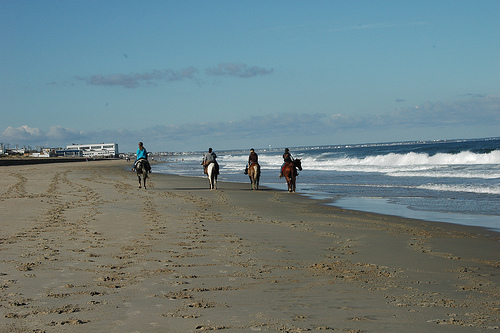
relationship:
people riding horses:
[133, 138, 298, 164] [130, 139, 309, 196]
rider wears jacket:
[132, 138, 154, 175] [135, 145, 150, 161]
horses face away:
[130, 139, 309, 196] [0, 1, 499, 180]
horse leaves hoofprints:
[201, 155, 221, 190] [212, 191, 500, 332]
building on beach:
[64, 140, 121, 165] [0, 136, 499, 332]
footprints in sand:
[0, 165, 500, 332] [0, 136, 499, 332]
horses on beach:
[130, 139, 309, 196] [0, 136, 499, 332]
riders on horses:
[133, 138, 298, 164] [130, 139, 309, 196]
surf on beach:
[134, 136, 500, 231] [0, 136, 499, 332]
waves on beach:
[182, 150, 500, 198] [0, 136, 499, 332]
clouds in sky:
[2, 13, 498, 148] [0, 0, 500, 152]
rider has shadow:
[132, 138, 154, 175] [149, 182, 211, 193]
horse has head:
[279, 156, 307, 195] [291, 157, 305, 171]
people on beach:
[133, 138, 298, 164] [0, 136, 499, 332]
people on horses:
[133, 138, 298, 164] [130, 139, 309, 196]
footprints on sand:
[0, 165, 500, 332] [0, 136, 499, 332]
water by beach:
[134, 136, 500, 231] [0, 136, 499, 332]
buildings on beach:
[0, 139, 121, 166] [0, 136, 499, 332]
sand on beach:
[0, 136, 499, 332] [0, 155, 499, 333]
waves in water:
[182, 150, 500, 198] [134, 136, 500, 231]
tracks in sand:
[0, 165, 500, 332] [0, 136, 499, 332]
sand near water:
[0, 136, 499, 332] [134, 136, 500, 231]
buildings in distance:
[0, 139, 121, 166] [0, 1, 499, 180]